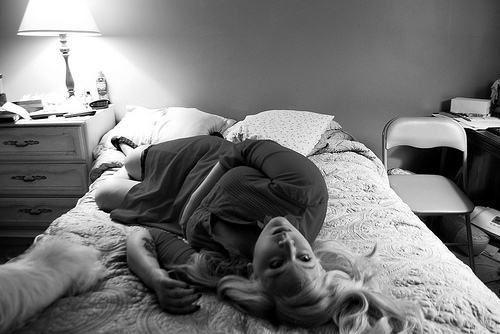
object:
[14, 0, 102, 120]
lamp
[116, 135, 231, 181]
leg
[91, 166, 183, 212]
leg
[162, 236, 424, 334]
hair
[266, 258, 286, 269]
eyes/woman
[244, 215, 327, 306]
head woman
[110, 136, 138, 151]
shoe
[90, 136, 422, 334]
woman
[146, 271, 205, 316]
hand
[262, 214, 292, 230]
chin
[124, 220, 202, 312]
arm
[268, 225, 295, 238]
mouth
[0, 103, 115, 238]
stand